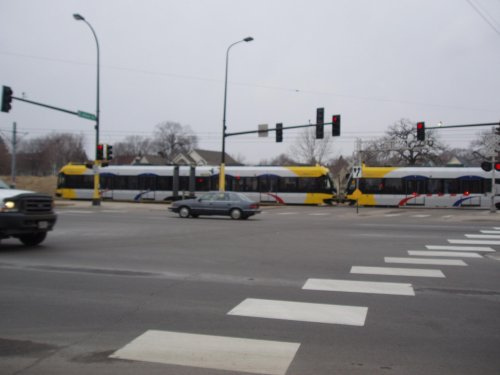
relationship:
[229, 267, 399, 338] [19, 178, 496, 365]
box in road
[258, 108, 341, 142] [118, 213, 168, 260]
signals in road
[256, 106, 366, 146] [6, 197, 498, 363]
signals in road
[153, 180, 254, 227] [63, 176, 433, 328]
car in road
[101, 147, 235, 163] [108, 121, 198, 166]
roofs behind trees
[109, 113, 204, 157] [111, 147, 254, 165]
trees in front of roofs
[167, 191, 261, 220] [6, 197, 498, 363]
car on road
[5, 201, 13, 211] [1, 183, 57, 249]
headlight on truck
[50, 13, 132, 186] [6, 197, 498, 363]
post next to road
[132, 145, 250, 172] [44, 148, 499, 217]
house behind train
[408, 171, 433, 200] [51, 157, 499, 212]
door on train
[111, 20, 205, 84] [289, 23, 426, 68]
clouds in sky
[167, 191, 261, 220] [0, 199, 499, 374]
car in road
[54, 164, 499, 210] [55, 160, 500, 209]
train has train